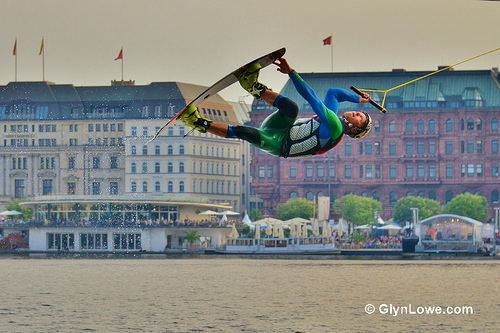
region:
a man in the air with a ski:
[153, 42, 374, 167]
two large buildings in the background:
[6, 71, 496, 205]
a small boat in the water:
[225, 232, 334, 252]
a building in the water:
[21, 190, 213, 259]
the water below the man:
[2, 255, 499, 330]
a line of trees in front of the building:
[250, 195, 494, 235]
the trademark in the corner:
[364, 299, 479, 321]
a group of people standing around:
[339, 236, 404, 249]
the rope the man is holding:
[346, 44, 496, 109]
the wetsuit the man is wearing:
[221, 87, 352, 163]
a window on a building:
[13, 178, 25, 195]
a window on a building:
[41, 177, 51, 194]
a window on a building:
[89, 181, 101, 192]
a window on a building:
[108, 180, 118, 192]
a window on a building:
[92, 157, 100, 167]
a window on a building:
[109, 156, 116, 170]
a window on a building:
[23, 124, 28, 132]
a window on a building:
[168, 145, 171, 157]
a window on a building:
[166, 180, 171, 193]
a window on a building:
[178, 180, 185, 191]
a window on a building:
[388, 143, 396, 153]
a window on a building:
[389, 162, 400, 182]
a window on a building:
[385, 119, 397, 135]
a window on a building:
[403, 120, 413, 132]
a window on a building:
[416, 119, 424, 133]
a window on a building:
[443, 119, 453, 135]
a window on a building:
[443, 140, 451, 152]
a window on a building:
[443, 165, 455, 181]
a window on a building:
[470, 159, 477, 179]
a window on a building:
[491, 137, 497, 154]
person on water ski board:
[146, 47, 374, 160]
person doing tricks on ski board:
[141, 36, 371, 156]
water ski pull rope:
[345, 57, 491, 112]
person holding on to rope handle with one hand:
[325, 66, 427, 146]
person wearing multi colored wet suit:
[182, 57, 417, 164]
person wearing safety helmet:
[332, 99, 392, 151]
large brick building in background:
[243, 62, 492, 220]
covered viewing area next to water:
[12, 190, 234, 230]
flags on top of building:
[7, 37, 138, 91]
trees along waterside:
[337, 191, 490, 226]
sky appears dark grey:
[2, 2, 495, 74]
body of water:
[5, 258, 496, 329]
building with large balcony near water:
[20, 191, 235, 276]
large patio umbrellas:
[195, 205, 346, 251]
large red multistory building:
[247, 67, 493, 218]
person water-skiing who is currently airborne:
[146, 37, 376, 298]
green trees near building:
[247, 155, 490, 231]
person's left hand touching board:
[225, 40, 342, 151]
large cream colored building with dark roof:
[5, 77, 247, 208]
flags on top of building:
[0, 28, 133, 133]